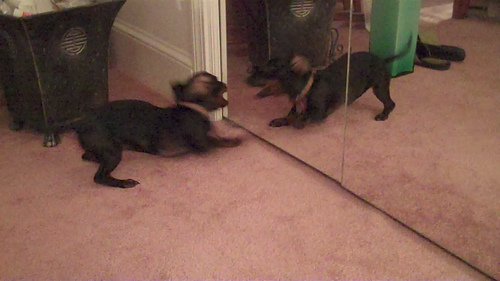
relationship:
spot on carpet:
[141, 263, 174, 280] [3, 65, 499, 280]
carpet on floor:
[3, 65, 499, 280] [3, 18, 496, 280]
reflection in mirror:
[243, 25, 404, 130] [223, 2, 493, 259]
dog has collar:
[68, 70, 250, 192] [178, 98, 213, 126]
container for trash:
[367, 0, 421, 80] [1, 0, 100, 21]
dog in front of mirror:
[68, 70, 250, 192] [223, 2, 493, 259]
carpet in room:
[3, 65, 499, 280] [0, 0, 495, 277]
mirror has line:
[223, 2, 493, 259] [336, 117, 350, 174]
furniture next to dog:
[4, 23, 113, 105] [86, 72, 243, 185]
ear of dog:
[191, 71, 215, 93] [68, 70, 250, 192]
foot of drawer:
[39, 131, 63, 149] [4, 0, 124, 151]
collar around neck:
[173, 98, 212, 118] [176, 94, 213, 123]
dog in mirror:
[68, 70, 250, 192] [223, 2, 493, 259]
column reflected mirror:
[363, 0, 425, 82] [223, 2, 493, 259]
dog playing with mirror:
[68, 70, 250, 192] [223, 2, 493, 259]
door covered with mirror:
[251, 6, 488, 278] [223, 2, 493, 259]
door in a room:
[0, 0, 488, 278] [0, 0, 495, 277]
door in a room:
[339, 0, 499, 279] [0, 0, 495, 277]